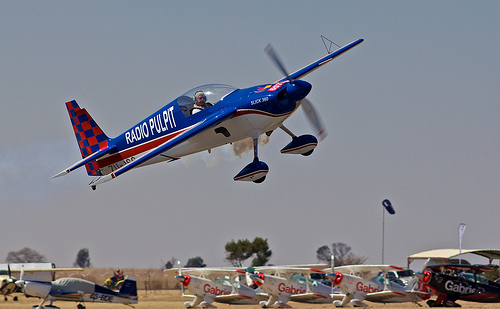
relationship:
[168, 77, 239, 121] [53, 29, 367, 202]
cockpit of aircraft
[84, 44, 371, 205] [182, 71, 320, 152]
plane has cockpit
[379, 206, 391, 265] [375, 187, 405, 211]
pole has wind sock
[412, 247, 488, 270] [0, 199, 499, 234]
canopy in background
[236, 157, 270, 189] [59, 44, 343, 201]
wheel on plane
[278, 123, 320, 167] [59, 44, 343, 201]
wheel on plane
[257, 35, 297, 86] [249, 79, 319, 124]
propeller blade on nose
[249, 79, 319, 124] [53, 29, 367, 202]
nose on aircraft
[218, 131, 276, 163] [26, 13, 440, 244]
smoke coming out of a plane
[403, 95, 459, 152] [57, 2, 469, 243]
clouds in sky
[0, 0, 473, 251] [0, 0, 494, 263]
clouds in sky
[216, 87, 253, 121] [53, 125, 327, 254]
paint on plane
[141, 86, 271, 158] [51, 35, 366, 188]
paint on plane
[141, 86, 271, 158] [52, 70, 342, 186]
paint on plane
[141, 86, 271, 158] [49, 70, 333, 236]
paint on plane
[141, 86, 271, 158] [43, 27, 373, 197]
paint on plane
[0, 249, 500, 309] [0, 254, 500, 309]
aircraft on field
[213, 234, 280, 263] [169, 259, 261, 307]
tree behind parked plane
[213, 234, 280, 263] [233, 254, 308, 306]
tree behind parked plane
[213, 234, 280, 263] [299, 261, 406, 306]
tree behind parked plane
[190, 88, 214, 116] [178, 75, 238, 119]
pilot sitting in cockpit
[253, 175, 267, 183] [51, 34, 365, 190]
wheel on aircraft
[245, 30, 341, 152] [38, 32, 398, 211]
propeller on plane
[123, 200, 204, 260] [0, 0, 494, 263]
clouds in sky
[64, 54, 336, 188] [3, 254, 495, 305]
aircraft on field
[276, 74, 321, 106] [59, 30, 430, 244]
nose hub on aircraft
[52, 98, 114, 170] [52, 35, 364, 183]
tail on aircraft